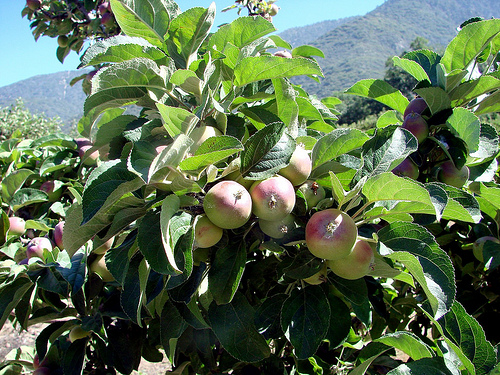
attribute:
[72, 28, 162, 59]
leaf — in the sun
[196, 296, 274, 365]
leaf — in the shade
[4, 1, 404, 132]
hill — in the distance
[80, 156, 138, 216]
leaf — dark green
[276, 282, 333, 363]
leaf — in the shade, dark green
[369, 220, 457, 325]
leaf — dark green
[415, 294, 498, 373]
leaf — dark green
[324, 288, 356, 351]
leaf — dark green